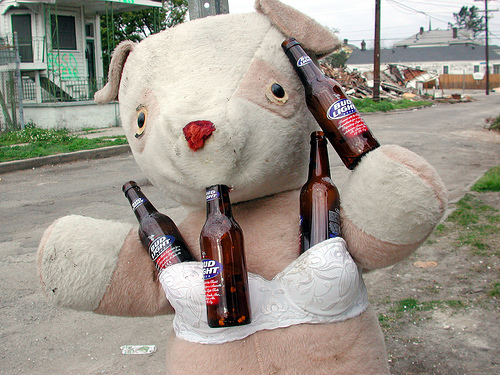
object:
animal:
[35, 0, 447, 374]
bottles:
[122, 35, 380, 329]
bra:
[157, 236, 366, 344]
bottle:
[200, 185, 253, 328]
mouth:
[206, 181, 232, 194]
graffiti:
[44, 50, 80, 84]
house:
[0, 1, 164, 135]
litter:
[119, 343, 157, 354]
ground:
[0, 88, 499, 374]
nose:
[182, 120, 217, 151]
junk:
[318, 63, 442, 100]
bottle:
[282, 37, 380, 170]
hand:
[340, 145, 447, 268]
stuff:
[205, 266, 250, 325]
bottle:
[123, 179, 196, 273]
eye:
[135, 108, 147, 134]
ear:
[93, 40, 132, 105]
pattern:
[157, 236, 372, 344]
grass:
[1, 123, 127, 171]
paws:
[34, 214, 141, 318]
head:
[93, 0, 339, 212]